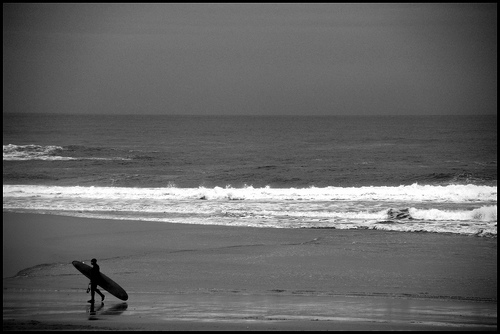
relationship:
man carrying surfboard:
[84, 258, 107, 303] [40, 244, 153, 310]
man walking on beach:
[84, 258, 107, 303] [0, 114, 497, 326]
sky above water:
[5, 1, 499, 111] [0, 114, 499, 240]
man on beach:
[84, 258, 107, 303] [27, 264, 486, 331]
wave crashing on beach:
[3, 180, 497, 235] [0, 208, 499, 331]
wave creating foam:
[3, 175, 498, 245] [157, 175, 499, 202]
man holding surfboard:
[84, 258, 107, 303] [71, 260, 132, 303]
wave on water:
[3, 180, 497, 235] [0, 114, 499, 240]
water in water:
[286, 118, 373, 148] [0, 114, 499, 240]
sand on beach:
[0, 222, 215, 249] [0, 114, 497, 326]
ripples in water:
[0, 158, 498, 189] [260, 127, 394, 202]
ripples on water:
[0, 158, 498, 189] [426, 157, 484, 206]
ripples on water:
[70, 152, 454, 182] [6, 111, 498, 232]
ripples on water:
[0, 158, 498, 189] [233, 112, 429, 232]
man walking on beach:
[84, 256, 106, 306] [0, 208, 499, 331]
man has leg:
[84, 256, 106, 306] [95, 287, 105, 300]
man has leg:
[84, 256, 106, 306] [88, 287, 96, 303]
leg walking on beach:
[95, 287, 105, 300] [0, 208, 499, 331]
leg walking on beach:
[88, 287, 96, 303] [0, 208, 499, 331]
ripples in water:
[0, 158, 498, 189] [6, 111, 498, 232]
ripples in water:
[3, 137, 132, 164] [6, 111, 498, 232]